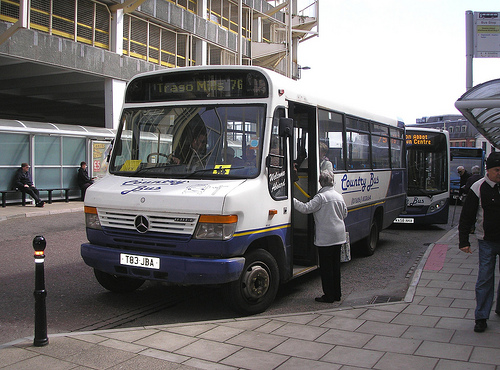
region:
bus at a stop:
[77, 62, 404, 310]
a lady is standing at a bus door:
[283, 145, 355, 305]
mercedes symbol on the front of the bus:
[128, 202, 160, 234]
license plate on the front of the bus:
[117, 250, 166, 273]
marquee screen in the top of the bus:
[133, 63, 265, 98]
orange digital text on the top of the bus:
[404, 128, 439, 147]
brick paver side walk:
[10, 218, 497, 365]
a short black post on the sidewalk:
[29, 227, 49, 348]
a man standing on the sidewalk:
[455, 144, 499, 331]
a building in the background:
[2, 0, 299, 202]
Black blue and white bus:
[82, 43, 412, 324]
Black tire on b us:
[223, 228, 299, 310]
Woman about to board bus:
[284, 147, 357, 327]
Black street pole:
[27, 223, 59, 346]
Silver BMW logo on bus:
[128, 216, 155, 237]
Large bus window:
[103, 91, 268, 185]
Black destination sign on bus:
[403, 122, 445, 157]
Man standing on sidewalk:
[450, 147, 499, 369]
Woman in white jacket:
[289, 171, 363, 253]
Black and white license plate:
[117, 245, 174, 281]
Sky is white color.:
[335, 7, 442, 93]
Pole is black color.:
[20, 230, 62, 345]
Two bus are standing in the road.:
[107, 57, 460, 274]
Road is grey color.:
[0, 222, 101, 317]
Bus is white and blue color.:
[108, 72, 412, 279]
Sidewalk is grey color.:
[261, 310, 476, 368]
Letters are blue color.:
[333, 166, 386, 201]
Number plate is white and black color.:
[113, 250, 168, 275]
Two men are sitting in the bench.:
[12, 157, 92, 210]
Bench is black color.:
[3, 185, 90, 212]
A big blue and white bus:
[75, 60, 414, 315]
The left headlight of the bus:
[190, 210, 242, 243]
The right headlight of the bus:
[81, 205, 103, 233]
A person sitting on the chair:
[8, 161, 49, 210]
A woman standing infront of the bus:
[291, 165, 351, 306]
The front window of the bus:
[101, 98, 270, 185]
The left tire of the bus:
[221, 243, 285, 318]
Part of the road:
[61, 270, 85, 312]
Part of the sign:
[482, 37, 492, 52]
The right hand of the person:
[458, 238, 473, 255]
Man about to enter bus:
[273, 164, 363, 311]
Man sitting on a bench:
[12, 157, 46, 204]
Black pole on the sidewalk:
[19, 229, 64, 352]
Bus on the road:
[76, 62, 409, 302]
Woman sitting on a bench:
[72, 154, 102, 197]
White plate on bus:
[111, 245, 168, 277]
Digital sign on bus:
[378, 122, 450, 155]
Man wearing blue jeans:
[455, 144, 499, 336]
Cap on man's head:
[480, 146, 499, 168]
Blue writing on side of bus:
[336, 164, 385, 194]